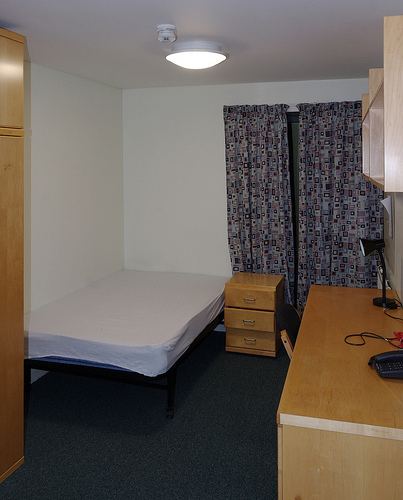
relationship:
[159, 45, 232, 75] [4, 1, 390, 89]
ceiling light on ceiling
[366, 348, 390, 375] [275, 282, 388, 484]
phone on desk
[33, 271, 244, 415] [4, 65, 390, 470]
bed in room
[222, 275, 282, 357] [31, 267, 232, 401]
cabinet near bed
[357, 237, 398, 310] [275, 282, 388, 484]
lamp on desk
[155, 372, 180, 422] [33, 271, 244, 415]
leg on bed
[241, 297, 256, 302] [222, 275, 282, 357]
handle on cabinet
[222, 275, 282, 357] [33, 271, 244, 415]
cabinet near bed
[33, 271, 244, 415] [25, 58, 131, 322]
bed against wall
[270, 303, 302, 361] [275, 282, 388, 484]
chair sitting at desk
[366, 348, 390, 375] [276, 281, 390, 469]
phone at desk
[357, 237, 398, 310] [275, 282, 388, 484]
lamp at desk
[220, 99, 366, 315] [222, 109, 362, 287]
curtain on window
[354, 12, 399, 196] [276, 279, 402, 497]
wall shelf above desk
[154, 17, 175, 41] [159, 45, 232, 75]
smoke alarm next to ceiling light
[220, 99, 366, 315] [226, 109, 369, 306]
curtain on window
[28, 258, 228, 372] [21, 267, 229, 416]
sheet on bed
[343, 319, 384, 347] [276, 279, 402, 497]
cord on desk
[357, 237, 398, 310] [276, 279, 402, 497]
lamp on desk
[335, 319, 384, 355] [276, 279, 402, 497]
cord on desk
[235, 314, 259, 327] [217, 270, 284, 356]
handle on dresser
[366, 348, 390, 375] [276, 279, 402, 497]
phone on desk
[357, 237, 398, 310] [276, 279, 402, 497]
lamp sitting on a desk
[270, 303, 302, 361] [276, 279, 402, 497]
chair under desk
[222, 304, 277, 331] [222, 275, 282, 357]
drawers on cabinet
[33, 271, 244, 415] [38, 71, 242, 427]
bed in corner